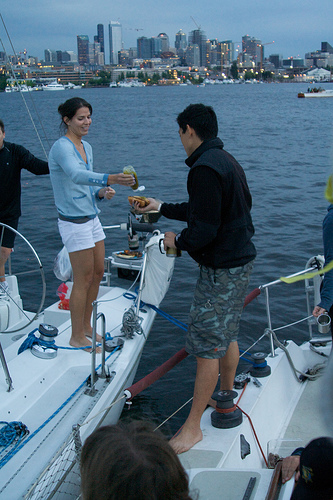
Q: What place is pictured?
A: It is a marina.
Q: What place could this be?
A: It is a marina.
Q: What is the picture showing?
A: It is showing a marina.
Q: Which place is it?
A: It is a marina.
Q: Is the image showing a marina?
A: Yes, it is showing a marina.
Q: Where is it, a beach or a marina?
A: It is a marina.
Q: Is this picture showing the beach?
A: No, the picture is showing the marina.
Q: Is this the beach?
A: No, it is the marina.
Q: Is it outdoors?
A: Yes, it is outdoors.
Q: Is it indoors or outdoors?
A: It is outdoors.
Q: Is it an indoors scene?
A: No, it is outdoors.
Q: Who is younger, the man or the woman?
A: The woman is younger than the man.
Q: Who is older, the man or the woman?
A: The man is older than the woman.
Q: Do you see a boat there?
A: Yes, there is a boat.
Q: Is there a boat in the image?
A: Yes, there is a boat.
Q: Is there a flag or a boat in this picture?
A: Yes, there is a boat.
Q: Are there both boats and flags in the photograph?
A: No, there is a boat but no flags.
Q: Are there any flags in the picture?
A: No, there are no flags.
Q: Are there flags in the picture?
A: No, there are no flags.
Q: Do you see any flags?
A: No, there are no flags.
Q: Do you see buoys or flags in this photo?
A: No, there are no flags or buoys.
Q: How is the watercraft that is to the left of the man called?
A: The watercraft is a boat.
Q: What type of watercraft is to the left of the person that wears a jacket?
A: The watercraft is a boat.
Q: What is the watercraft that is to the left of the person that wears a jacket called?
A: The watercraft is a boat.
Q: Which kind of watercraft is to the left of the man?
A: The watercraft is a boat.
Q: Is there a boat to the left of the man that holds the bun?
A: Yes, there is a boat to the left of the man.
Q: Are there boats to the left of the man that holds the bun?
A: Yes, there is a boat to the left of the man.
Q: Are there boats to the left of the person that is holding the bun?
A: Yes, there is a boat to the left of the man.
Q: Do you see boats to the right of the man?
A: No, the boat is to the left of the man.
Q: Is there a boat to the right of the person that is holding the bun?
A: No, the boat is to the left of the man.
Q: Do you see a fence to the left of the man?
A: No, there is a boat to the left of the man.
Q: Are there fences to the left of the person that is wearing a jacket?
A: No, there is a boat to the left of the man.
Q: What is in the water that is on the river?
A: The boat is in the water.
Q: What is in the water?
A: The boat is in the water.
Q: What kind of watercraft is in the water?
A: The watercraft is a boat.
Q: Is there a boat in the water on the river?
A: Yes, there is a boat in the water.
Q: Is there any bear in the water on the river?
A: No, there is a boat in the water.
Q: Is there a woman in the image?
A: Yes, there is a woman.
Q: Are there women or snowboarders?
A: Yes, there is a woman.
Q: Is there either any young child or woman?
A: Yes, there is a young woman.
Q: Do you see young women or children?
A: Yes, there is a young woman.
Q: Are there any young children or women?
A: Yes, there is a young woman.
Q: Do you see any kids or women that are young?
A: Yes, the woman is young.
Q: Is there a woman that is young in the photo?
A: Yes, there is a young woman.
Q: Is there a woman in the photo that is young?
A: Yes, there is a woman that is young.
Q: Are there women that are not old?
A: Yes, there is an young woman.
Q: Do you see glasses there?
A: No, there are no glasses.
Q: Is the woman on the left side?
A: Yes, the woman is on the left of the image.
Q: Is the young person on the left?
A: Yes, the woman is on the left of the image.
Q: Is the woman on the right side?
A: No, the woman is on the left of the image.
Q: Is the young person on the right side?
A: No, the woman is on the left of the image.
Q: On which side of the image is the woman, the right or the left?
A: The woman is on the left of the image.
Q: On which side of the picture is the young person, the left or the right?
A: The woman is on the left of the image.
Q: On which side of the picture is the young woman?
A: The woman is on the left of the image.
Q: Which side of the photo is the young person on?
A: The woman is on the left of the image.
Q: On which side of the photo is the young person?
A: The woman is on the left of the image.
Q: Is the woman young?
A: Yes, the woman is young.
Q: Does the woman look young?
A: Yes, the woman is young.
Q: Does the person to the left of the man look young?
A: Yes, the woman is young.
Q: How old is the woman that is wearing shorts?
A: The woman is young.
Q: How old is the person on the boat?
A: The woman is young.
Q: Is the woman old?
A: No, the woman is young.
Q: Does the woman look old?
A: No, the woman is young.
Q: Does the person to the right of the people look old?
A: No, the woman is young.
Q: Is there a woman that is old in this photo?
A: No, there is a woman but she is young.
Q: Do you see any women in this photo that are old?
A: No, there is a woman but she is young.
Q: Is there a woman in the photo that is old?
A: No, there is a woman but she is young.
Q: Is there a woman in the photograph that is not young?
A: No, there is a woman but she is young.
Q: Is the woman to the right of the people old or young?
A: The woman is young.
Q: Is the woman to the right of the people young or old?
A: The woman is young.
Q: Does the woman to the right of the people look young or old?
A: The woman is young.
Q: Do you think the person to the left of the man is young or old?
A: The woman is young.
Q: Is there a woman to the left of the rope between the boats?
A: Yes, there is a woman to the left of the rope.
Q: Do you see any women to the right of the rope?
A: No, the woman is to the left of the rope.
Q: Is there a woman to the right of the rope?
A: No, the woman is to the left of the rope.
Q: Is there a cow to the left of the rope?
A: No, there is a woman to the left of the rope.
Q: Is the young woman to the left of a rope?
A: Yes, the woman is to the left of a rope.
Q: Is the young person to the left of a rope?
A: Yes, the woman is to the left of a rope.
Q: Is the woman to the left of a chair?
A: No, the woman is to the left of a rope.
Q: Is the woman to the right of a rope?
A: No, the woman is to the left of a rope.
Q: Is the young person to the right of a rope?
A: No, the woman is to the left of a rope.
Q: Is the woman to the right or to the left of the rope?
A: The woman is to the left of the rope.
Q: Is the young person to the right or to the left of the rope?
A: The woman is to the left of the rope.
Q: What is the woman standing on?
A: The woman is standing on the boat.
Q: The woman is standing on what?
A: The woman is standing on the boat.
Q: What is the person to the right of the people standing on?
A: The woman is standing on the boat.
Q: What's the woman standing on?
A: The woman is standing on the boat.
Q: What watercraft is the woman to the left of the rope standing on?
A: The woman is standing on the boat.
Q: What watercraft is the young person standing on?
A: The woman is standing on the boat.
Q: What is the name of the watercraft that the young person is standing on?
A: The watercraft is a boat.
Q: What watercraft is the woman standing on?
A: The woman is standing on the boat.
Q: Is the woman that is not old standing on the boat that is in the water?
A: Yes, the woman is standing on the boat.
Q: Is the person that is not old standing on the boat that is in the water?
A: Yes, the woman is standing on the boat.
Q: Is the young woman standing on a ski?
A: No, the woman is standing on the boat.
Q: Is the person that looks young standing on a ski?
A: No, the woman is standing on the boat.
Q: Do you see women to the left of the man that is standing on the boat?
A: Yes, there is a woman to the left of the man.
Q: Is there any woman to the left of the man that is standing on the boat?
A: Yes, there is a woman to the left of the man.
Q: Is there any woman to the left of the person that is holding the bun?
A: Yes, there is a woman to the left of the man.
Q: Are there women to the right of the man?
A: No, the woman is to the left of the man.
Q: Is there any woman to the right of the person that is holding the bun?
A: No, the woman is to the left of the man.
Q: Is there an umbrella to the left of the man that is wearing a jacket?
A: No, there is a woman to the left of the man.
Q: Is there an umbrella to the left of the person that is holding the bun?
A: No, there is a woman to the left of the man.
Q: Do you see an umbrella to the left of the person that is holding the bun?
A: No, there is a woman to the left of the man.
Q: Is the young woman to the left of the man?
A: Yes, the woman is to the left of the man.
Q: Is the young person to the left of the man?
A: Yes, the woman is to the left of the man.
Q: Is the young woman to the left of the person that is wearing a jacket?
A: Yes, the woman is to the left of the man.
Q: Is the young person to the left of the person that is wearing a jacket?
A: Yes, the woman is to the left of the man.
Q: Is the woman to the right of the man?
A: No, the woman is to the left of the man.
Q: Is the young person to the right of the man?
A: No, the woman is to the left of the man.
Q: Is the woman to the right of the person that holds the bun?
A: No, the woman is to the left of the man.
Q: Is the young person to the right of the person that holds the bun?
A: No, the woman is to the left of the man.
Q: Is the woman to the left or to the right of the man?
A: The woman is to the left of the man.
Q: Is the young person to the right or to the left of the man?
A: The woman is to the left of the man.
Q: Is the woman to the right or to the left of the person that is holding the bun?
A: The woman is to the left of the man.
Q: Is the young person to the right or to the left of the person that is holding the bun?
A: The woman is to the left of the man.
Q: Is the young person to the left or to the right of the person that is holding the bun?
A: The woman is to the left of the man.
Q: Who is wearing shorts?
A: The woman is wearing shorts.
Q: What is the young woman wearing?
A: The woman is wearing shorts.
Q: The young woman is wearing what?
A: The woman is wearing shorts.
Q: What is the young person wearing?
A: The woman is wearing shorts.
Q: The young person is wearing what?
A: The woman is wearing shorts.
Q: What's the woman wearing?
A: The woman is wearing shorts.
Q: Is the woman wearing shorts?
A: Yes, the woman is wearing shorts.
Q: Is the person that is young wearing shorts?
A: Yes, the woman is wearing shorts.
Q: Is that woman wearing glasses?
A: No, the woman is wearing shorts.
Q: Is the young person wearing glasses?
A: No, the woman is wearing shorts.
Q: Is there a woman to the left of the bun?
A: Yes, there is a woman to the left of the bun.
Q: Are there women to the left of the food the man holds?
A: Yes, there is a woman to the left of the bun.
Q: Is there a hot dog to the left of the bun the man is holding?
A: No, there is a woman to the left of the bun.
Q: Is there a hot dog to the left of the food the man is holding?
A: No, there is a woman to the left of the bun.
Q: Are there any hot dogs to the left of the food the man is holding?
A: No, there is a woman to the left of the bun.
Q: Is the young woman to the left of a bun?
A: Yes, the woman is to the left of a bun.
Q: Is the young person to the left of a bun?
A: Yes, the woman is to the left of a bun.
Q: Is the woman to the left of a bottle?
A: No, the woman is to the left of a bun.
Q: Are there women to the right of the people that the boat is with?
A: Yes, there is a woman to the right of the people.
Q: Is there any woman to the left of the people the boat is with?
A: No, the woman is to the right of the people.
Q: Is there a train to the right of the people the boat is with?
A: No, there is a woman to the right of the people.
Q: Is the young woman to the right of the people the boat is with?
A: Yes, the woman is to the right of the people.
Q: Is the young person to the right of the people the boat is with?
A: Yes, the woman is to the right of the people.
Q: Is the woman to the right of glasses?
A: No, the woman is to the right of the people.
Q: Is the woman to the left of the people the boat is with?
A: No, the woman is to the right of the people.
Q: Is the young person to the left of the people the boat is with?
A: No, the woman is to the right of the people.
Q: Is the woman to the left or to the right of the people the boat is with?
A: The woman is to the right of the people.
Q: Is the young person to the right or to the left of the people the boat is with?
A: The woman is to the right of the people.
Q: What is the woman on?
A: The woman is on the boat.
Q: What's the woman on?
A: The woman is on the boat.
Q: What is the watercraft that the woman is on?
A: The watercraft is a boat.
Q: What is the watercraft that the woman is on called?
A: The watercraft is a boat.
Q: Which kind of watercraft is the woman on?
A: The woman is on the boat.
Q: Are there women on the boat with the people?
A: Yes, there is a woman on the boat.